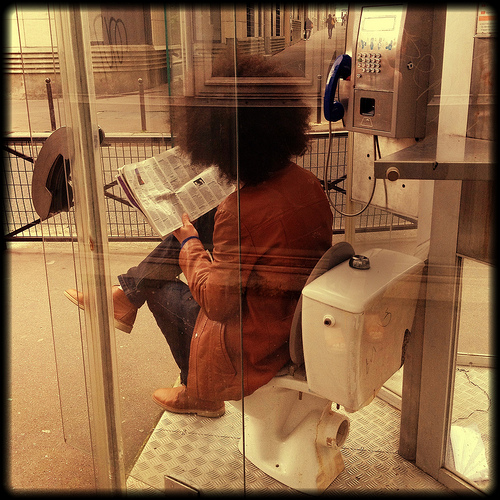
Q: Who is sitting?
A: A woman reading the newspaper.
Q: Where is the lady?
A: Telephone booth.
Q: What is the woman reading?
A: Newspaper.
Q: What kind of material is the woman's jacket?
A: Leather.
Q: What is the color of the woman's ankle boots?
A: Brown.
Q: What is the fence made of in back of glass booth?
A: Metal.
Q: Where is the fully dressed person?
A: On toilet.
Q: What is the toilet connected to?
A: Nothing.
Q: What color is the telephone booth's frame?
A: Silver.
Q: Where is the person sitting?
A: On a toilet.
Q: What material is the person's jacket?
A: Leather.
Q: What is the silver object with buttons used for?
A: Making telephone calls.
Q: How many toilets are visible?
A: 1.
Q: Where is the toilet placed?
A: Telephone booth.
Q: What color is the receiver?
A: Black.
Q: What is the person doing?
A: Reading.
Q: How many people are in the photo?
A: One.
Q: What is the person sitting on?
A: Toilet.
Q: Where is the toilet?
A: Phone booth.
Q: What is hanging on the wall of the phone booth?
A: Pay phone.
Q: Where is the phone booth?
A: Sidewalk.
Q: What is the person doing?
A: Reading newspaper.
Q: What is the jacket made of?
A: Leather.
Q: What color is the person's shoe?
A: Dark tan.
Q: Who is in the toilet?
A: A man.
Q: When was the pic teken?
A: During the day.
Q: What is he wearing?
A: Jacket.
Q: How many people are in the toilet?
A: 1.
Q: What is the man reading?
A: Newspaper.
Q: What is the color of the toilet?
A: White.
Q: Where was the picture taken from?
A: On toilet.